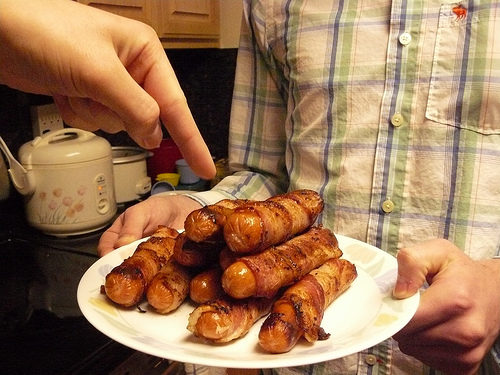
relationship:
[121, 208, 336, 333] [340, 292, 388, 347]
food on plate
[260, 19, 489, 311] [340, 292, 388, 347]
person holding plate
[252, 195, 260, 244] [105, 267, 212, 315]
bacon on hot dogs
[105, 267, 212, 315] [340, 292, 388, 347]
hot dogs on plate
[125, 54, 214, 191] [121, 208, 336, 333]
finger pointing at food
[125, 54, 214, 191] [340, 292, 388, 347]
finger pointing at plate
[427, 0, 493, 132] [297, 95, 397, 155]
pocket on shirt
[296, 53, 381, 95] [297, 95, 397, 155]
stripes on shirt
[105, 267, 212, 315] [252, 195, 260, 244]
hot dogs wrapped in bacon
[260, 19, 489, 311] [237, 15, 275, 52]
person wearing plaid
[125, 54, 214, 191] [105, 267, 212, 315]
finger pointing at hot dogs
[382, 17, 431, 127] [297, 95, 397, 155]
buttons on shirt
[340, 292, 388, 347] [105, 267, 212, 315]
plate has hot dogs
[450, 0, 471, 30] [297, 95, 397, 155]
emblem on shirt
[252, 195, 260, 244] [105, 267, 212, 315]
bacon wrapped on hot dogs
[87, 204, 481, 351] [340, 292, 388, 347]
hands holding onto plate